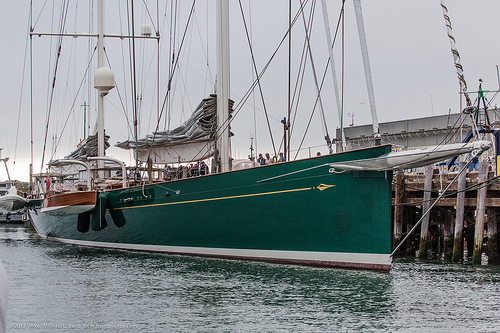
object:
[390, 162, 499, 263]
dock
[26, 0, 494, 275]
boat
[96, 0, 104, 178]
mast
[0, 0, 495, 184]
sky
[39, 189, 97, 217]
lifeboat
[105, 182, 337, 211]
arrow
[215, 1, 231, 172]
mast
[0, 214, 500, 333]
water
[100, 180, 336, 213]
stripe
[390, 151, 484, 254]
columns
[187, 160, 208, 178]
crowd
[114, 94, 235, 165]
sail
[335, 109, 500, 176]
building